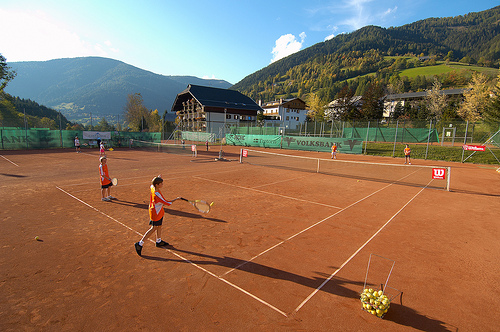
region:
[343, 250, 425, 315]
a basket of tennis balls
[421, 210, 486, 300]
orange clay of a tennis court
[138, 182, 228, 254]
a tennis player swinging a racket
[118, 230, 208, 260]
player has on black shoes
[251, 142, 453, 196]
a tennis court net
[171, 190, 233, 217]
a tennis racket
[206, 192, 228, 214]
a tennis ball flying through the air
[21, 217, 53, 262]
a tennis ball lying on the ground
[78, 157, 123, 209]
person in black skirt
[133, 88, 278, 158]
a chalet in the distance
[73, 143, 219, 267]
the two people are playing tennis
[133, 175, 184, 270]
this person has black tennis shoes on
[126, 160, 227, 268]
this person is swinging their raquette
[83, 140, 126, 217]
this person is just standing there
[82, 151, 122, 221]
the person has on white tennis shoes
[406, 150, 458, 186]
there is a Wilson insignia on the net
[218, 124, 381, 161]
the banner in the back is green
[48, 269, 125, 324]
the court is clay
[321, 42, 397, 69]
the hills are covered in trees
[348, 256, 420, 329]
basket of yellow balls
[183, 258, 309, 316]
white lines on court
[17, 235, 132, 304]
red clay on tennis court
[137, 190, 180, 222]
orange and white jersey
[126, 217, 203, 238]
black tennis shorts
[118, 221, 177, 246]
small size white socks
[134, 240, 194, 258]
player wearing black sneakers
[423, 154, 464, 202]
large red and white sign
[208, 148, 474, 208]
net across tennis court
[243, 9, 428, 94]
large green mountain range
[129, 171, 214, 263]
Boy swinging tennis racquet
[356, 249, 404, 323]
Tennis ball hopper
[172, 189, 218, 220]
Tennis racquet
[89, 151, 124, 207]
Boy holding tennis racquet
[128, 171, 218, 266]
Boy playing tennis on a clay court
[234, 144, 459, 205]
Tennis court net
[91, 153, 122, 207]
Boy wearing orange shirt and holding tennis racquet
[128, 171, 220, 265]
Boy hitting a tennis ball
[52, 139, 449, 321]
Clay tennis court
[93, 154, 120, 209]
Boy with a tennis racquet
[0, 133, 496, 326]
two red clay tennis courts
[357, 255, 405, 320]
a bag full of tennis balls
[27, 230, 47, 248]
a tennis ball behind the players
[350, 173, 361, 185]
a tennis ball near the net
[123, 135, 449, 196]
two nets on the courts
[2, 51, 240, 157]
mountains on the horizon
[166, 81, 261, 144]
a chalet next to the courts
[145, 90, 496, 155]
a small hamlet in the mountains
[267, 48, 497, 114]
fields of green on the hillside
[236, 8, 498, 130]
tree covered hills and mountains